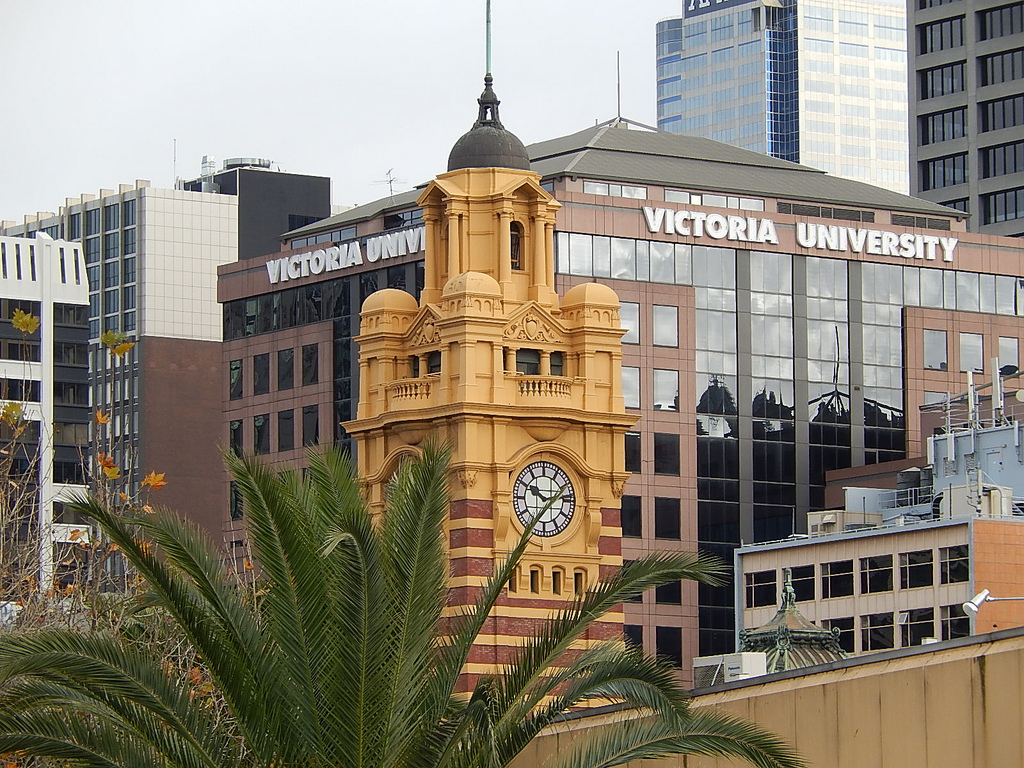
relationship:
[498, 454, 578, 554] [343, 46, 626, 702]
clock on tower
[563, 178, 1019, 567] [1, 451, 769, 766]
building in front of tree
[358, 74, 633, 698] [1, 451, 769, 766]
building in front of tree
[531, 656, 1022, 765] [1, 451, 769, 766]
building in front of tree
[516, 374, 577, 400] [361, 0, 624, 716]
balcony on top of tower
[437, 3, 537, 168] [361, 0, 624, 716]
steeple atop of tower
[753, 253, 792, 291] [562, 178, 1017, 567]
window on building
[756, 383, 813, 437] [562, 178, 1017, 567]
window on building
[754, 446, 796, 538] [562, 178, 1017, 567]
window on building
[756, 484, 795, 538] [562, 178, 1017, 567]
window on building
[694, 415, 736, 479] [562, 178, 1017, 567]
window on building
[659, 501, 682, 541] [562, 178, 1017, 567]
window on building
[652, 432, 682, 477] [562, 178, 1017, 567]
window on building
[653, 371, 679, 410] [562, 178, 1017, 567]
window on building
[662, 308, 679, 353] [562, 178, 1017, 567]
window on building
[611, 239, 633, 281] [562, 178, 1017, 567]
window on building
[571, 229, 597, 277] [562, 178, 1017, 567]
window on building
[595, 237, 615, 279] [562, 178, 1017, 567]
window on building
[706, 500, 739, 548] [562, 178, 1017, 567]
window on building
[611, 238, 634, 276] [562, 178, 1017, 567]
window on building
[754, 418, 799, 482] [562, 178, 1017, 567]
window on building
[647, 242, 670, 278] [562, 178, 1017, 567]
window on building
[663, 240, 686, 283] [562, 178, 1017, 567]
window on building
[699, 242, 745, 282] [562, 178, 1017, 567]
window on building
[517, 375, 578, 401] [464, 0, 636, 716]
balcony on side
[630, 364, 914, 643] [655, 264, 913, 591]
reflection in windows